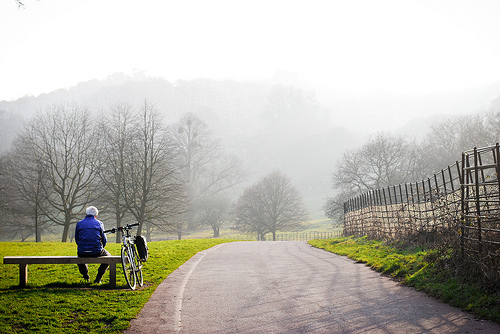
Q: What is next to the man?
A: Mountain bike.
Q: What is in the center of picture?
A: Gray pavement on path.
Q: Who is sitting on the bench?
A: Man wearing blue jacket.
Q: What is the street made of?
A: Asphalt.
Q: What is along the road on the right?
A: A fence.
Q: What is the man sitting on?
A: A bench.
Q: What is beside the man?
A: A bike.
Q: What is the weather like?
A: Overcast.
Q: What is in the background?
A: Trees.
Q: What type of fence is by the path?
A: Wooden.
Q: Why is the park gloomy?
A: Fog.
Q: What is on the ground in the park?
A: Grass.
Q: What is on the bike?
A: A backpack.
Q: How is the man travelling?
A: By bike.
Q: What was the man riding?
A: Bike.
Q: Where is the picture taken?
A: In the country.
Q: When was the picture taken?
A: During the daytime.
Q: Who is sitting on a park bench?
A: Man wearing a blue coat.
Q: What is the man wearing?
A: Blue coat.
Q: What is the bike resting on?
A: Bench.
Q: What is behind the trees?
A: A hill.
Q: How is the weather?
A: Foggy.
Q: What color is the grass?
A: Green.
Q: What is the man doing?
A: Sitting.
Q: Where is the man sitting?
A: On the bench.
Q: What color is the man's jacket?
A: Blue.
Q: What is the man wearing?
A: Hat.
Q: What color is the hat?
A: White.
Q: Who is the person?
A: A man.